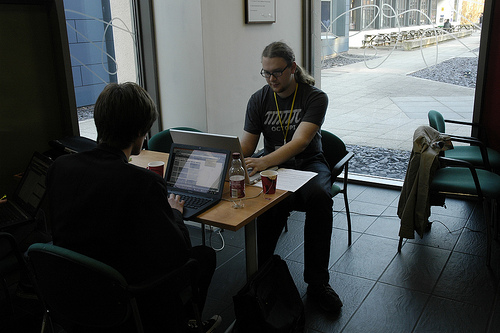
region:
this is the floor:
[357, 259, 453, 314]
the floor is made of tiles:
[362, 264, 477, 329]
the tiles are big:
[366, 270, 475, 330]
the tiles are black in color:
[354, 253, 379, 269]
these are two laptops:
[153, 129, 248, 202]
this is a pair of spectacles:
[261, 65, 291, 82]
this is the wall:
[175, 20, 205, 44]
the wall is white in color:
[182, 14, 218, 79]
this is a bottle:
[226, 150, 246, 211]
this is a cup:
[261, 164, 281, 194]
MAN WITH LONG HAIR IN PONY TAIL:
[243, 38, 331, 100]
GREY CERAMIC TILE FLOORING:
[332, 223, 414, 303]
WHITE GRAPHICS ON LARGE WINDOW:
[323, 3, 492, 66]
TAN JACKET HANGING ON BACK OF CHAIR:
[386, 122, 457, 250]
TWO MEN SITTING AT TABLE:
[68, 33, 344, 218]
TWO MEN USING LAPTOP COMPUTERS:
[66, 26, 338, 217]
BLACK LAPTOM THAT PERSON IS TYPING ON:
[161, 124, 232, 219]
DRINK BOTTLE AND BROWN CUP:
[223, 149, 293, 209]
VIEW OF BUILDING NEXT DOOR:
[68, 15, 141, 99]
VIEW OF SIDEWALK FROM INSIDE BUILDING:
[328, 9, 483, 170]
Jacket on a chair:
[395, 114, 495, 254]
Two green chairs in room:
[380, 80, 493, 244]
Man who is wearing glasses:
[237, 30, 335, 114]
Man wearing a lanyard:
[223, 35, 337, 185]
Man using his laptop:
[163, 27, 343, 177]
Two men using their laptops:
[44, 23, 389, 267]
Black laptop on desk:
[144, 136, 246, 234]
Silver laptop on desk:
[158, 112, 278, 180]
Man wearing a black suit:
[45, 73, 224, 306]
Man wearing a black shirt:
[229, 27, 371, 223]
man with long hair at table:
[228, 16, 354, 251]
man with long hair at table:
[58, 58, 172, 285]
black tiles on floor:
[381, 259, 466, 331]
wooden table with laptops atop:
[108, 113, 282, 250]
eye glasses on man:
[245, 67, 294, 87]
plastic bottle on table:
[228, 144, 250, 219]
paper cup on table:
[253, 165, 278, 202]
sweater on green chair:
[382, 123, 457, 233]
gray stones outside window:
[356, 148, 416, 185]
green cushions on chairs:
[418, 106, 490, 171]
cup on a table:
[258, 164, 280, 198]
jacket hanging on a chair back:
[404, 121, 446, 238]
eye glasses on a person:
[258, 67, 289, 85]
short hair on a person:
[94, 84, 142, 145]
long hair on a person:
[264, 25, 326, 97]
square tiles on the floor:
[355, 253, 400, 330]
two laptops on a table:
[162, 115, 247, 223]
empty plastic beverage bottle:
[228, 157, 248, 211]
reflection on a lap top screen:
[185, 150, 222, 200]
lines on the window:
[68, 14, 130, 81]